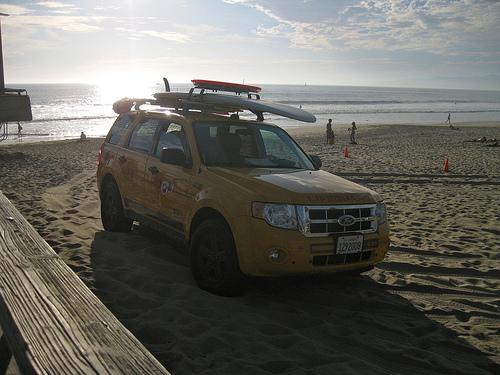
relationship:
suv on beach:
[92, 103, 394, 294] [1, 121, 499, 372]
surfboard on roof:
[154, 86, 319, 125] [124, 100, 279, 124]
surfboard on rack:
[154, 86, 319, 125] [163, 79, 265, 123]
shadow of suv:
[91, 227, 497, 373] [92, 103, 394, 294]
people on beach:
[326, 115, 360, 143] [1, 121, 499, 372]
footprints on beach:
[57, 177, 93, 285] [1, 121, 499, 372]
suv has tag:
[92, 103, 394, 294] [334, 232, 366, 254]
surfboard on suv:
[154, 86, 319, 125] [92, 103, 394, 294]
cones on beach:
[342, 145, 454, 171] [1, 121, 499, 372]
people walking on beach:
[326, 115, 360, 143] [1, 121, 499, 372]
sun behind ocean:
[97, 50, 161, 84] [4, 82, 499, 121]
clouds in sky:
[7, 3, 496, 89] [8, 3, 499, 89]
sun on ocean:
[97, 50, 161, 84] [4, 82, 499, 121]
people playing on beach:
[326, 115, 360, 143] [1, 121, 499, 372]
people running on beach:
[326, 115, 360, 143] [1, 121, 499, 372]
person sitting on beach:
[81, 128, 89, 141] [1, 121, 499, 372]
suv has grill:
[92, 103, 394, 294] [310, 206, 377, 229]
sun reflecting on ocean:
[97, 50, 161, 84] [4, 82, 499, 121]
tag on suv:
[334, 232, 366, 254] [92, 103, 394, 294]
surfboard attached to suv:
[154, 86, 319, 125] [92, 103, 394, 294]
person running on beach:
[445, 109, 455, 127] [1, 121, 499, 372]